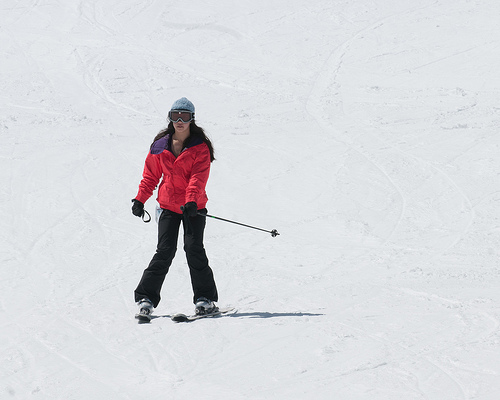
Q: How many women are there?
A: One.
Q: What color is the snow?
A: White.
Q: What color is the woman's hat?
A: Blue.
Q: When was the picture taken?
A: Daytime.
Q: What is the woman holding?
A: Ski poles.